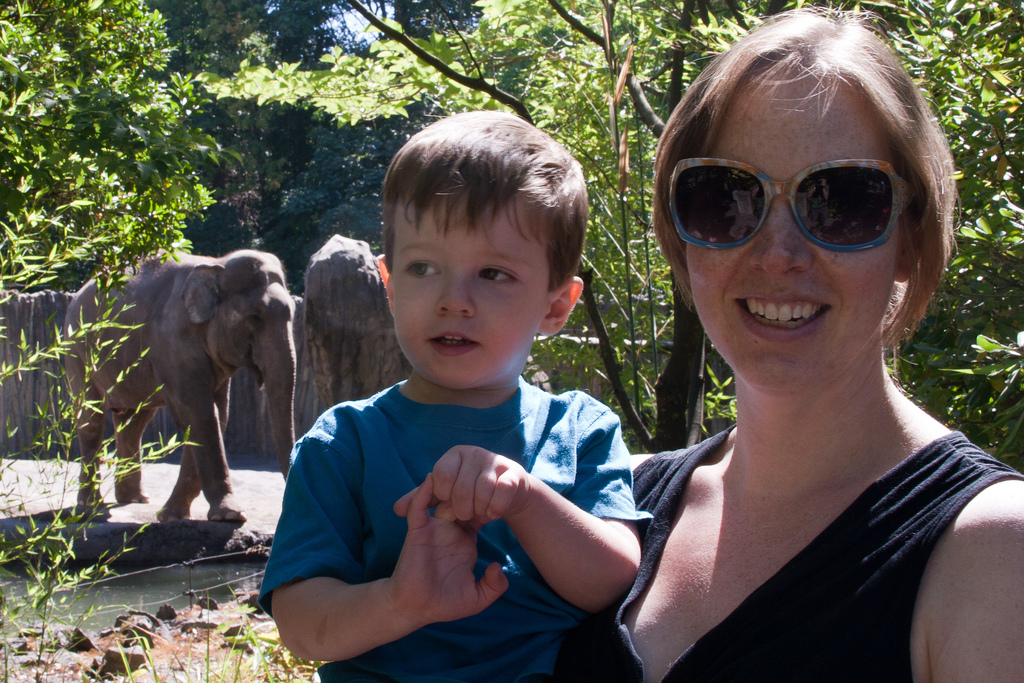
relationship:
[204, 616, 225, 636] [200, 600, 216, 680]
leaf on stem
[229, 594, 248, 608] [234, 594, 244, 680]
leaf on stem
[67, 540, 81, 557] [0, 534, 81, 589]
leaf on stem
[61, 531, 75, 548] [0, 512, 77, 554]
leaf on stem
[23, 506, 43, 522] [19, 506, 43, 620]
leaf on stem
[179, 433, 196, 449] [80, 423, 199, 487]
leaf growing on stem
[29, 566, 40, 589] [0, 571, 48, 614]
leaf growing on stem